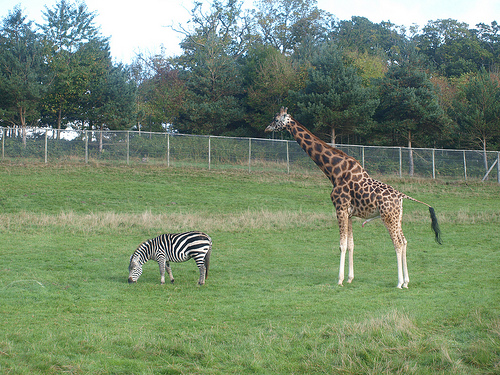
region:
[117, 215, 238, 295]
zebra is small and striped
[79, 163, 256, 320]
A zebra and giraffe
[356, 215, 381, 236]
A happy giraffe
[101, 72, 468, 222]
A giraffe in the enclosure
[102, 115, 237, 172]
A chain link fence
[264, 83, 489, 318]
The giraffe is in the field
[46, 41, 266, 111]
Trees in the background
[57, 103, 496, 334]
Small enclosure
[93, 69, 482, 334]
Animals at a zoo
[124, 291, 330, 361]
Green grass in the pasture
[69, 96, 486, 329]
Animals at the zoo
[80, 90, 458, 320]
a zebra and giraffe in a field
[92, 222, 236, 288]
a zebra eating grass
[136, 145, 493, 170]
a long chain link fence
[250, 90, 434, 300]
a giraffe that is urinating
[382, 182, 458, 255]
a giraffe's tail sticking out.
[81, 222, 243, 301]
a zebra with its head down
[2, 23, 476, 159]
a line of trees near a fence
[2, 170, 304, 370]
a field of green grass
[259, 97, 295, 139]
horns on a giraffes head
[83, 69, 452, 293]
a zebra standing in front of a giraffe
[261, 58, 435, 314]
Giraffe in the field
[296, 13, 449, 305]
Giraffe is happy to see the zebra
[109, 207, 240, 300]
Little zebra eating grass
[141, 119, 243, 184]
Chain link fence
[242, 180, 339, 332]
Grass field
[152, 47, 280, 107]
Trees behind the fence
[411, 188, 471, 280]
Giraffe tail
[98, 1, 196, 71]
White sky above the animals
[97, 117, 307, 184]
Chain link fence used for the enclosure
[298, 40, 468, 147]
Pine trees along the fence line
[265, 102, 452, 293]
giraffe standing on grass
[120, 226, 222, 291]
zebra grazing on grass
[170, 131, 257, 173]
chain link fence on hill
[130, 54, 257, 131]
trees behind chain link fence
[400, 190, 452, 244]
giraffe tail with black hair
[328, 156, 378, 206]
brown spots on giraffe body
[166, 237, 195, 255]
black and white stripes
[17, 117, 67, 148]
trunks of trees behind fence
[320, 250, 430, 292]
four white legs of giraffe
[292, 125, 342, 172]
long neck of giraffe